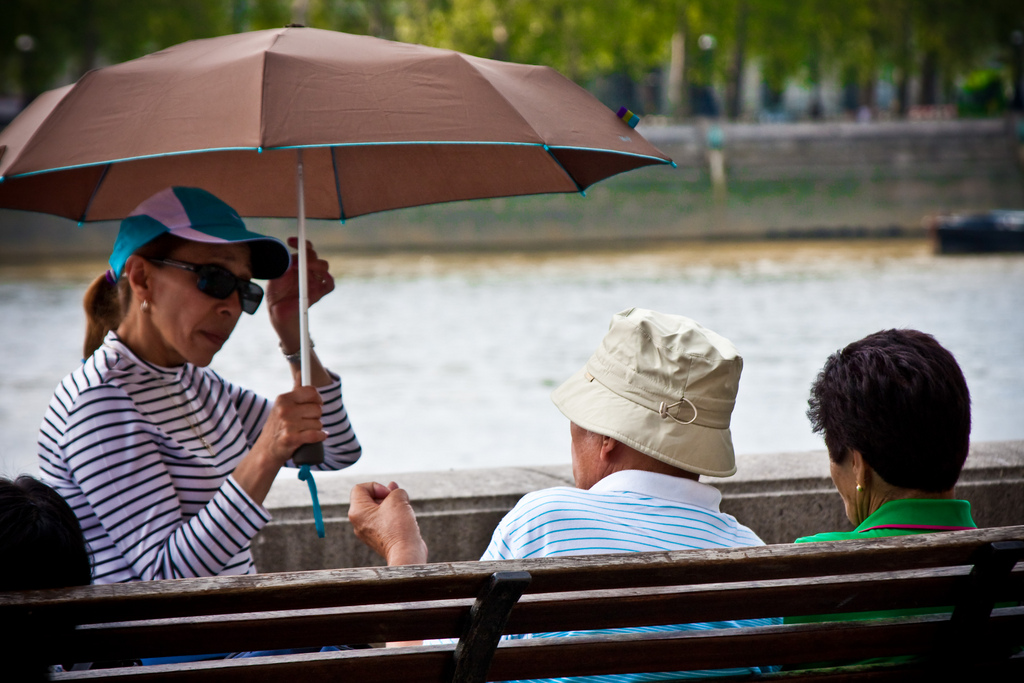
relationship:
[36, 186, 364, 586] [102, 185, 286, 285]
woman wearing hat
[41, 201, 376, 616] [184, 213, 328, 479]
woman holding umbrella